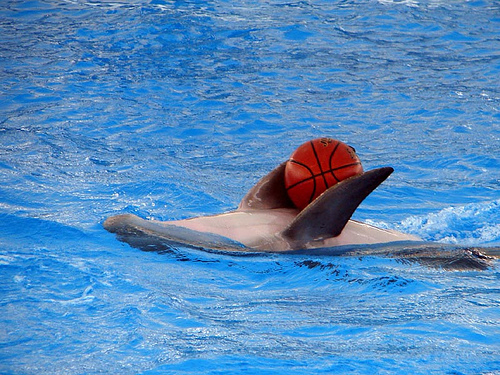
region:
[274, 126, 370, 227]
THIS IS A BASKET BALL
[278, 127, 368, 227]
THE BALL IS ORANGE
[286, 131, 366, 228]
THE DOLPHIN HAS THE BALL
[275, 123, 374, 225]
THE BALL IS WET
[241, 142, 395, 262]
THE DOLPHIN HAS FLIPPERS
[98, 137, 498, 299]
THE DOLPHIN IS IN THE WATER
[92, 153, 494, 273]
THE DOLPHIN IS ON IT'S BACK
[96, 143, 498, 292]
THIS IS A DOLPHIN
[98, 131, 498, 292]
THE DOLPHIN IS DOING A TRICK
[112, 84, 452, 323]
a dolphin in water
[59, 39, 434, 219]
the water is clear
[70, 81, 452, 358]
the dolphin is gray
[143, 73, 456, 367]
the dolphin is holding a ball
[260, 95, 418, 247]
the ball is orange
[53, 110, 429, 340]
the dolphin is flip over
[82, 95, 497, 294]
the dolphin is holding the ball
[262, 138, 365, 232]
the ball is orange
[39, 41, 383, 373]
a dolphin in a pool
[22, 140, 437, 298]
the dolphin is cute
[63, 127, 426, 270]
seal holding basketball in water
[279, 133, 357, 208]
basketball held by seal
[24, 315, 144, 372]
blue water in tank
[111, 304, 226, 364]
blue water in tank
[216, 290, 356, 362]
blue water in tank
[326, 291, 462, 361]
blue water in tank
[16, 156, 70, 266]
blue water in tank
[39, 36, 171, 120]
blue water in tank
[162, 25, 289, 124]
blue water in tank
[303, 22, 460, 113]
blue water in tank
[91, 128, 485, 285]
a dolphin holding a ball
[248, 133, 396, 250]
a baseball ball holding by two dolphin fins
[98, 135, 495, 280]
dolphin is upside down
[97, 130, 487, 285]
dolphin is in the water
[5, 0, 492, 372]
a blue body of water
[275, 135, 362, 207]
basketball ball is orange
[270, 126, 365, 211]
basketball ball has stripes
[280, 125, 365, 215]
stripes of basketball ball are black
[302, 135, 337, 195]
a straight line in the center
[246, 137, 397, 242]
fins of dolphin are gray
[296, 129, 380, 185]
orange basketball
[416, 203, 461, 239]
white waves in water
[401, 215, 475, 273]
darker grey color on dolphin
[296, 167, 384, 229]
dark grey fin on the front of dolphin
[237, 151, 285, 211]
dark grey fin on back of dolphin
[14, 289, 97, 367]
area of blue water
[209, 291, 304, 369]
area of blue water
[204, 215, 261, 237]
light pink color on dolphin's chest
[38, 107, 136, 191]
light blue area of water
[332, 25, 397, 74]
blue area of water